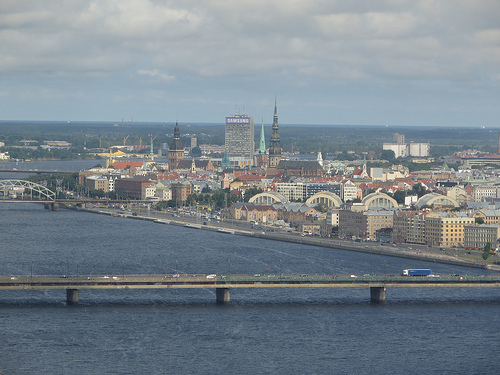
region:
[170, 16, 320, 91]
sky above the land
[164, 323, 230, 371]
water next to the bridge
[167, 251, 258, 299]
cars on the bridge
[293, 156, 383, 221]
buildings on the land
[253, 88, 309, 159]
tall building in the city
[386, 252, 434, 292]
truck on the bridge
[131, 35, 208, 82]
clouds in the sky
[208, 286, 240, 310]
pillar below the bridge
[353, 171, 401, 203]
red roofs on the ouse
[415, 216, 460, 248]
windows on the building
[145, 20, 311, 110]
clouds above the land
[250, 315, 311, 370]
water below the bridge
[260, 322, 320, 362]
ripples in the water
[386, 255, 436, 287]
blue and white truck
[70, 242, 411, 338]
bridge above the water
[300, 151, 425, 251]
buildings on the land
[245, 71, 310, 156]
tall tower amongst many buildings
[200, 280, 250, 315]
pillar under the bridge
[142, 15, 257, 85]
sky above the land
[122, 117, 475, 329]
city next to water and bridge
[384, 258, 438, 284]
the blue color bridge on the dam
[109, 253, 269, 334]
the dam on the river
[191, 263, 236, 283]
the white color car on the dam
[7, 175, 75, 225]
the white color bridge on the river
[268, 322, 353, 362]
the water in the river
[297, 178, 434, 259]
the buildings on the river side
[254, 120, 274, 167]
the green color building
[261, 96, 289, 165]
the tower in the middle of the buildings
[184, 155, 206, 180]
the church in middle of the buildings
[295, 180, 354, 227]
the bridge in middle of the houses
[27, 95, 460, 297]
panoramic picture of a city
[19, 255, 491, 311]
cars and trucks on the bridge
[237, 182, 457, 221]
yellow archways on the top of a building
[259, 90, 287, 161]
tallest steeple in the city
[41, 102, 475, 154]
flat land in the far distance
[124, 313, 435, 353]
river water appears calm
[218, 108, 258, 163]
tallest office building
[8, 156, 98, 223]
two bridges in the background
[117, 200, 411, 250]
cars can drive on the street next to the water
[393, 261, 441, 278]
large blue and white truck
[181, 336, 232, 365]
the water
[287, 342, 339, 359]
the water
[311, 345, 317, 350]
the water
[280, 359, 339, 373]
the water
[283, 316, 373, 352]
the water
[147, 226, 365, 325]
the water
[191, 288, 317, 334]
the water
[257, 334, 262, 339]
the water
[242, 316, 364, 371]
the water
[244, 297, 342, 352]
the water